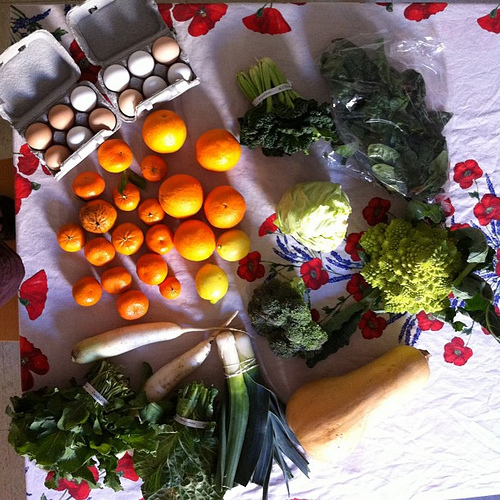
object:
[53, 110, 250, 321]
oranges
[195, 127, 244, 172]
orange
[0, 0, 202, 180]
carton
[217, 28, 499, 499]
vegetables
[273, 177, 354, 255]
cabbage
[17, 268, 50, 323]
flower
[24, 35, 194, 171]
eggs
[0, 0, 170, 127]
paper cartons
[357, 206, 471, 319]
squash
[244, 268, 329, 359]
brocolli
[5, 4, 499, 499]
foods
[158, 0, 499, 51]
red poppy pattern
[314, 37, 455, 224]
leaves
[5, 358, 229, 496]
lettuce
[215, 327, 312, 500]
leeks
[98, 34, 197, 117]
half dozen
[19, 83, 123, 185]
half a dozen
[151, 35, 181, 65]
egg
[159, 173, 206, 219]
orange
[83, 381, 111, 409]
tag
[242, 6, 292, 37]
red flowers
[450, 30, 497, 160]
wrinkles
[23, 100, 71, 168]
brown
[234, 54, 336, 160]
herbs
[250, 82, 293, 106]
twist ties